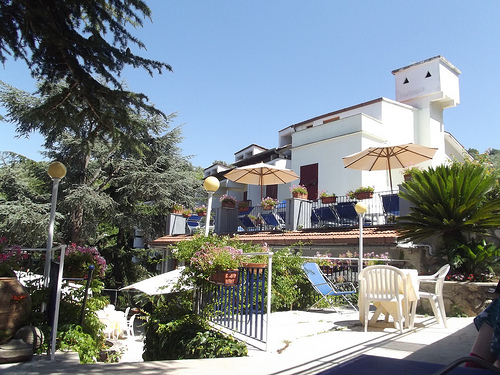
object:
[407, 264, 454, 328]
chairs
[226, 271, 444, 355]
patio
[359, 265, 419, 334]
chair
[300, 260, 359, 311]
chair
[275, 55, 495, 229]
building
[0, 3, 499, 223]
background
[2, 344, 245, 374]
path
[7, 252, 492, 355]
garden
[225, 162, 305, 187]
umbrellas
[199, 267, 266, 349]
bars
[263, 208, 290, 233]
chairs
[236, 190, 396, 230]
fence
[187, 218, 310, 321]
plants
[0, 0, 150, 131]
tree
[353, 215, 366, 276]
pole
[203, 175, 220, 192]
light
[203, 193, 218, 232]
pole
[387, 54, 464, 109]
part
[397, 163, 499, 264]
tree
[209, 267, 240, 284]
box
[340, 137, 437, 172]
umbrella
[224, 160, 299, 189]
umbrella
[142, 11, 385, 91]
sky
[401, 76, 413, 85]
shapes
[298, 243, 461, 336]
furniture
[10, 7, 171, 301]
distance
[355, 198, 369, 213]
globes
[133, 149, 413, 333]
poolside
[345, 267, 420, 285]
table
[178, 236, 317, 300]
shrubbery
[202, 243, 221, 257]
flowers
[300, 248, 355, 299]
frame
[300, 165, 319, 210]
door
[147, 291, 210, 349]
shrub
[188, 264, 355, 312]
railing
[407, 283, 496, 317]
wall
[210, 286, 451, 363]
concrete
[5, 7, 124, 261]
left